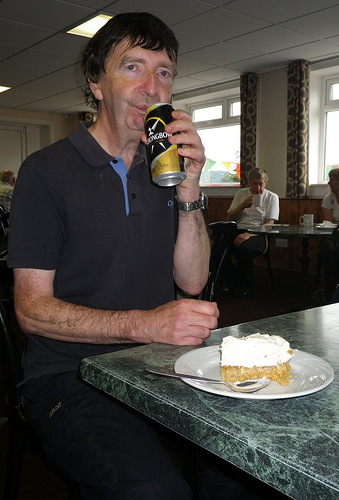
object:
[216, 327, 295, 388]
cake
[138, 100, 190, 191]
beer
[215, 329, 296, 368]
frosting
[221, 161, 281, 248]
man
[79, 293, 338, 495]
table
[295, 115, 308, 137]
pattern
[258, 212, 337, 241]
table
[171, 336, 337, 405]
plate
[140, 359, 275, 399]
spoon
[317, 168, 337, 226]
woman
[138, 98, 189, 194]
can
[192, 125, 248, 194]
window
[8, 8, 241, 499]
an old man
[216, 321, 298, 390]
piece of cake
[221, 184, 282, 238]
white shirt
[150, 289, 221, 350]
man's right hand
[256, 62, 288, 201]
beige curtains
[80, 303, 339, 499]
marble painted table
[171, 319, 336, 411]
pie on round plate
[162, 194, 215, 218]
silver watch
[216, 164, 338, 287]
woman talking to man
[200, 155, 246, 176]
string of flags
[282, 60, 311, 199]
brown curtains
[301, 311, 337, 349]
marble top table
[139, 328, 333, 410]
plate with spoon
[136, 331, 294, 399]
cake and spoon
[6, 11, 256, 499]
an old man drinking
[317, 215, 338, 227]
slice of pie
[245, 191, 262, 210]
white coffee cup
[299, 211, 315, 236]
cup on a table